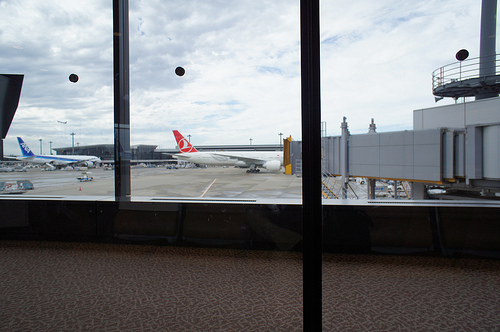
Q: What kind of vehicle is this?
A: Airplanes.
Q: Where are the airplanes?
A: Tarmac.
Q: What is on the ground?
A: Painted line.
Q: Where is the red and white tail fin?
A: On the plane in front.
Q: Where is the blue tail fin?
A: On the plane in the back.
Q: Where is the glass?
A: Airport window.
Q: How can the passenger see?
A: Through the glass.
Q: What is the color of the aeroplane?
A: White, red and blue.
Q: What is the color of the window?
A: Black.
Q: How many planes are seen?
A: 2.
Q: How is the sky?
A: Cloudy.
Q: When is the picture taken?
A: Daytime.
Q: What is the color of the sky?
A: White.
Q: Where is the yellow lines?
A: In the road.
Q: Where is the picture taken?
A: An airport.